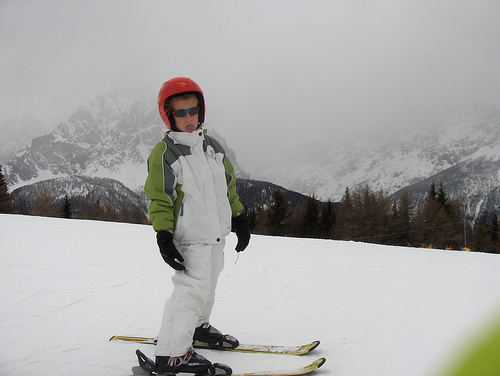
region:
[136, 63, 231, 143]
boy has red helmet on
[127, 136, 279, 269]
boy's jacket is green white and gray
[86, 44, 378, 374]
boy is on skis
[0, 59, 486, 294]
mountains are covered in snow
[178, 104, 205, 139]
boy's tongue is out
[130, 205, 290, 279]
boy's gloves are black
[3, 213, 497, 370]
ground covered in snow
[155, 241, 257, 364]
boy's pants are white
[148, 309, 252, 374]
boy has black ski shoes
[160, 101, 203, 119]
boy is wearing glasses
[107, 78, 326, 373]
young girl in skiing attire on a mountain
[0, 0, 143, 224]
mountains, trees, and the skyline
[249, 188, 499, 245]
a collection of dead brown trees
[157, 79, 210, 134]
girl wearing helmet and sunglasses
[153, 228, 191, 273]
black skiing glove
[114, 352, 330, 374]
right ski with ski boot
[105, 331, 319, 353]
left ski with ski boot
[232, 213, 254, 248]
black glove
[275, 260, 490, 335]
snow covered ground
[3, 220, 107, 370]
snow covered ground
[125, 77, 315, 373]
the kid is skiing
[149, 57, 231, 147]
boy wearing red ski helmet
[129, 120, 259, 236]
boy in green and white jacket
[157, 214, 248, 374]
boy wearing white snow pants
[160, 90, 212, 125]
boy wearing black goggles in photo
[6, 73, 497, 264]
snow covered mountains in background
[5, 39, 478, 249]
sky is foggy in photo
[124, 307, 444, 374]
boy on yellow and black skis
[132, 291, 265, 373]
boy wearing black ski boots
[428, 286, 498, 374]
something green in right hand corner of photo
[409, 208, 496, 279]
something yellow in background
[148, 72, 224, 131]
Boy wearing a red helmet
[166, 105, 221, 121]
Boy wearing dark glasses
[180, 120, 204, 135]
Boy sticking his tongue out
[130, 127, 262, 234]
Boy wearing warm jacket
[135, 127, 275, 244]
Boy's jacket is white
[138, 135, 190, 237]
White jacket has green sleeve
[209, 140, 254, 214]
White jacket has green sleeve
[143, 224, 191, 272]
Boy wearing black glove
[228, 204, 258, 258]
Boy wearing black glove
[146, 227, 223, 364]
Boy wearing white pants